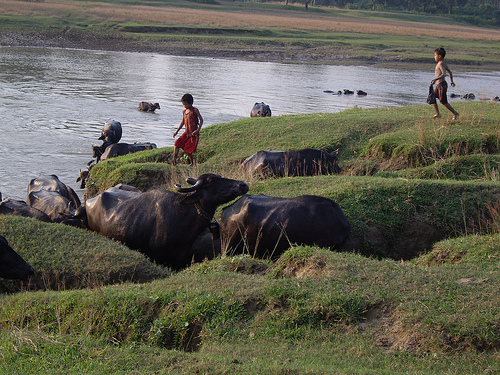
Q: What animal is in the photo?
A: Hippos.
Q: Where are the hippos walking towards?
A: The water.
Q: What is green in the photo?
A: Grass.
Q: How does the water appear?
A: Calm.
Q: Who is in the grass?
A: Two boys.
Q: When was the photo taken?
A: In the daytime.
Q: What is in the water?
A: Cows.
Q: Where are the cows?
A: In the hillside.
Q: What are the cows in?
A: A lake.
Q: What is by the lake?
A: The bank.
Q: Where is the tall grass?
A: On a hillside.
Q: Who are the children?
A: Native island children.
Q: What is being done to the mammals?
A: Being herded.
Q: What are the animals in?
A: Calm and clear river water.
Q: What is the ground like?
A: Flat grass and dirt.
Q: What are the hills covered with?
A: Grass.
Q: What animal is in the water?
A: A water buffalo.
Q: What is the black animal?
A: A water buffalo.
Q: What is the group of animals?
A: Water buffalo.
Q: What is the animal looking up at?
A: The boy.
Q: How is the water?
A: Calm and green.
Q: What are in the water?
A: Hippos.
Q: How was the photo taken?
A: With a telephoto lens.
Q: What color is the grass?
A: Green.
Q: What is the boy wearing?
A: Shorts.